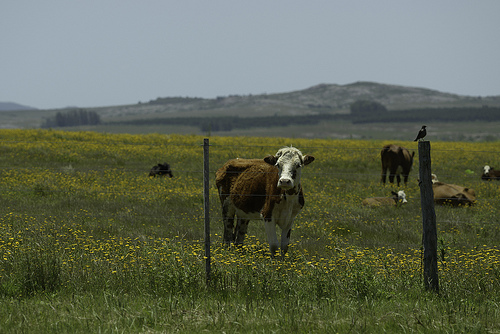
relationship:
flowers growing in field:
[58, 215, 203, 295] [34, 181, 206, 302]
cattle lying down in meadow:
[385, 142, 462, 206] [2, 128, 499, 331]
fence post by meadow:
[413, 137, 454, 284] [2, 128, 499, 331]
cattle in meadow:
[149, 161, 173, 178] [48, 138, 112, 158]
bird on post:
[412, 124, 428, 141] [416, 142, 448, 292]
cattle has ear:
[213, 148, 314, 257] [227, 144, 276, 166]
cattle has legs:
[213, 148, 314, 257] [213, 212, 286, 257]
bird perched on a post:
[412, 124, 428, 141] [415, 137, 440, 290]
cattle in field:
[197, 131, 326, 261] [2, 130, 498, 332]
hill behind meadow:
[314, 73, 426, 113] [66, 104, 499, 146]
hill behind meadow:
[202, 90, 319, 129] [66, 104, 499, 146]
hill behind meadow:
[102, 92, 212, 123] [66, 104, 499, 146]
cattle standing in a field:
[213, 148, 314, 257] [2, 130, 498, 332]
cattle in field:
[213, 148, 314, 257] [2, 130, 498, 332]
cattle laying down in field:
[149, 161, 173, 178] [2, 130, 498, 332]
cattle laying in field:
[479, 160, 500, 180] [11, 108, 169, 252]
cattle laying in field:
[149, 161, 173, 178] [2, 130, 498, 332]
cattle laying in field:
[213, 148, 314, 257] [2, 130, 498, 332]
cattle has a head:
[213, 148, 314, 257] [259, 140, 316, 190]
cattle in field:
[479, 160, 500, 180] [481, 162, 499, 179]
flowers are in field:
[271, 252, 277, 253] [2, 130, 498, 332]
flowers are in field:
[173, 251, 179, 258] [2, 130, 498, 332]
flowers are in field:
[173, 234, 183, 237] [2, 130, 498, 332]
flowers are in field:
[111, 270, 113, 274] [2, 130, 498, 332]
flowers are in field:
[386, 253, 393, 258] [2, 130, 498, 332]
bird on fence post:
[412, 124, 428, 141] [416, 141, 437, 290]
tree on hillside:
[92, 111, 101, 124] [5, 92, 387, 122]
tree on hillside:
[87, 109, 94, 124] [5, 92, 387, 122]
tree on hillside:
[82, 109, 89, 125] [5, 92, 387, 122]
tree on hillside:
[55, 110, 62, 125] [5, 92, 387, 122]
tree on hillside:
[65, 115, 72, 126] [5, 92, 387, 122]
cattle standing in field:
[213, 148, 314, 257] [27, 152, 212, 262]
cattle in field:
[380, 141, 416, 186] [2, 130, 498, 332]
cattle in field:
[361, 187, 408, 209] [2, 130, 498, 332]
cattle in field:
[479, 160, 496, 178] [2, 130, 498, 332]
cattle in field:
[417, 180, 477, 210] [2, 130, 498, 332]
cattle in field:
[149, 161, 171, 176] [2, 130, 498, 332]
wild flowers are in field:
[12, 251, 396, 286] [2, 130, 498, 332]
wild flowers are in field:
[3, 151, 163, 203] [2, 130, 498, 332]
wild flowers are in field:
[2, 122, 254, 160] [2, 130, 498, 332]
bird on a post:
[412, 124, 428, 141] [415, 141, 442, 289]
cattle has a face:
[213, 148, 314, 257] [277, 147, 297, 192]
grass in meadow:
[26, 276, 496, 321] [2, 128, 499, 331]